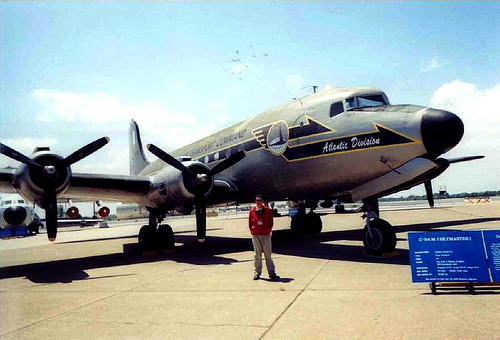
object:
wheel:
[359, 216, 395, 254]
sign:
[406, 228, 499, 284]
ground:
[0, 195, 499, 339]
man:
[247, 194, 282, 282]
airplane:
[0, 82, 486, 256]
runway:
[0, 196, 500, 338]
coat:
[246, 205, 274, 238]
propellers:
[145, 142, 249, 244]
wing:
[0, 161, 157, 205]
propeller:
[0, 134, 112, 244]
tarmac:
[0, 200, 499, 339]